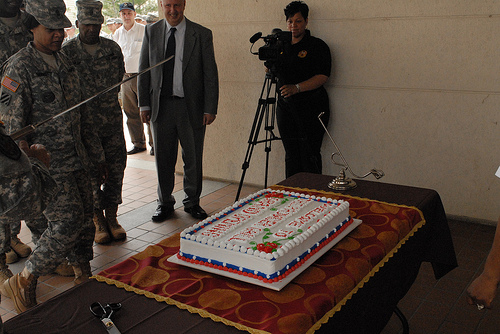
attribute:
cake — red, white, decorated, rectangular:
[171, 176, 363, 283]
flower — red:
[254, 240, 276, 255]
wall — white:
[171, 6, 498, 221]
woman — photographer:
[259, 1, 337, 182]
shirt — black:
[268, 33, 333, 106]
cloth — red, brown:
[99, 177, 431, 332]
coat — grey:
[134, 20, 221, 129]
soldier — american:
[63, 0, 134, 248]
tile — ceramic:
[127, 229, 150, 238]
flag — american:
[2, 75, 20, 93]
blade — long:
[10, 55, 179, 139]